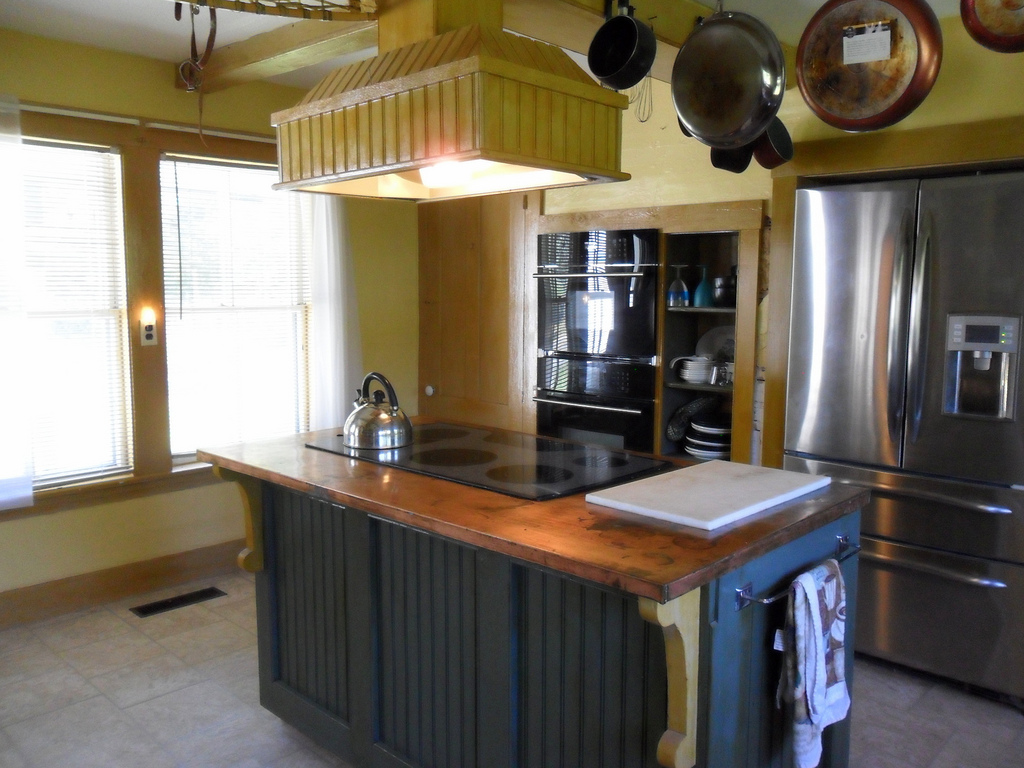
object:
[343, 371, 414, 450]
kettle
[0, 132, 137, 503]
window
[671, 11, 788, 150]
pan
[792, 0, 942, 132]
pan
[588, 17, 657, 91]
pan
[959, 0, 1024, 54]
pan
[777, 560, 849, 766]
towel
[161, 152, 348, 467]
window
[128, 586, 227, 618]
vent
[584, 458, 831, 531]
cutting board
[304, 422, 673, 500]
stove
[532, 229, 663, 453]
wall oven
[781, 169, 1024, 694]
refrigerator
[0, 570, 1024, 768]
floor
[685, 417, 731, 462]
plates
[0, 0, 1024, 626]
wall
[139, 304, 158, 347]
outlet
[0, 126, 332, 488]
scene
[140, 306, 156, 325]
light